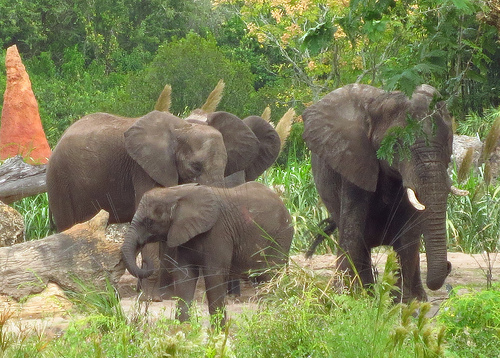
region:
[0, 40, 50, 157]
cone of red rock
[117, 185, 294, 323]
little baby elephant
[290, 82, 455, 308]
large african elephant adult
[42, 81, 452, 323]
three African Elephant adults and a baby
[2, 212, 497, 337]
large tree logs in the elephant enclosure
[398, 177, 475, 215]
two ivory elephant tusks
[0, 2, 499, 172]
densely growing trees in the background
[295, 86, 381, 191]
large elephant ear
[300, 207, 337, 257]
tuft of hair at the end of an elephant tail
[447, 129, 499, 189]
gray rock behind tall grass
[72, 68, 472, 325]
elephants that are standing outside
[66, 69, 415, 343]
elephants walking outside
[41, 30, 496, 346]
elephants in an area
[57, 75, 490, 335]
elephant walking in an area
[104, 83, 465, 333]
elephants in a field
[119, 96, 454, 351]
elephants walking in a field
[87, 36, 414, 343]
a field with elephants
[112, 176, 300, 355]
a small elephant walking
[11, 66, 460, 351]
an area with elephants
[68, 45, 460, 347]
elephants together in an area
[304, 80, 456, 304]
elephant is walking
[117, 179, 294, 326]
baby elephant is standing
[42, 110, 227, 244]
elephant is standing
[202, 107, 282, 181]
elephant is hidden in background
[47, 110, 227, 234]
elephant is in background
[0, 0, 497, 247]
vegetation is in background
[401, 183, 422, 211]
tusk belongs to elephant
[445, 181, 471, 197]
tusk belongs to elephant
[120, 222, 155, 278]
elephants trunk is curled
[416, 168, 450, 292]
trunk of elephant hangs down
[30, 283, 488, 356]
grass in front of the elephants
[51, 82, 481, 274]
elephants standing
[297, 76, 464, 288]
a large elephant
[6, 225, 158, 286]
a log next to the elephant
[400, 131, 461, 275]
the trunk of an elephant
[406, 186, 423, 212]
a white tusk on the elephant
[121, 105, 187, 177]
the ear on the elephant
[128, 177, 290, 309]
a small elephant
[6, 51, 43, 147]
a large rock behind the elephants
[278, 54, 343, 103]
a tree behind the elephant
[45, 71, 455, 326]
three elephants in a field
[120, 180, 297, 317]
a baby elephant in the center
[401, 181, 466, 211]
elephant on right has tusks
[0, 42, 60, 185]
a dirt road on the left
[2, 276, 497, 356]
high grass in front of elephants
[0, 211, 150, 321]
large log next to the elephants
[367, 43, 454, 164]
a tree branch covers the right elephant's eye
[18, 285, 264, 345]
baby elephant standing on a patch of sand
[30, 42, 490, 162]
lots of foilage behind the elephants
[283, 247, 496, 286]
sand behind the elephant on right